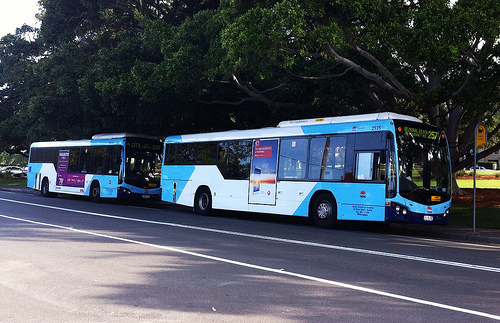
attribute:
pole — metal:
[470, 122, 480, 232]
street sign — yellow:
[473, 127, 489, 149]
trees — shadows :
[23, 13, 437, 135]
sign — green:
[387, 115, 445, 142]